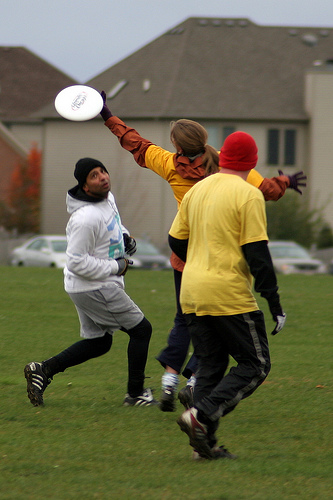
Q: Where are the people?
A: A field.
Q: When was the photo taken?
A: Daytime.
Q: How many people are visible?
A: Three.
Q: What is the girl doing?
A: Catching a frisbee.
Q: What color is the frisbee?
A: White.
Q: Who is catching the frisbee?
A: A girl.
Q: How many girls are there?
A: One.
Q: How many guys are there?
A: Two.